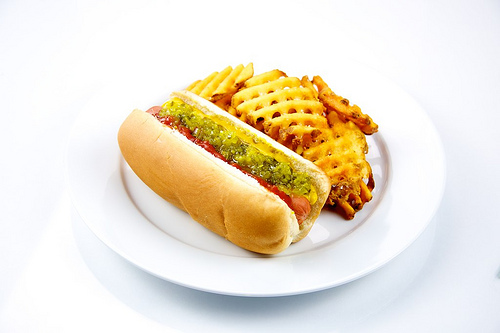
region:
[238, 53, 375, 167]
criss cut fries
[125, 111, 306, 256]
hotdog with bun and sauces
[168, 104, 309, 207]
mustard on a hotdog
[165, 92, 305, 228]
ketchup on a hotdog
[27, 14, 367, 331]
plate of food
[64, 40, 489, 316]
a white plate with food on it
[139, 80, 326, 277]
hotdog in a bun with mustard and ketchup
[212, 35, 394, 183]
potato fries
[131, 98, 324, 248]
A bun enclosing a hotdog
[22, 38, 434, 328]
A white clean plate containing good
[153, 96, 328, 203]
ketchup, mustard, and relish toppings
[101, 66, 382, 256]
a hotdog next to waffle fries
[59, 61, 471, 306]
a circular white plate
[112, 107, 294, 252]
a white bread hotdog bun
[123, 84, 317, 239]
a bun length hotdog.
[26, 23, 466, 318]
circular plate on a white surface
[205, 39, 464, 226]
waffle fries on a white plate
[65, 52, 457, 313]
a white plate under food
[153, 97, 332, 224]
relish in between ketchup and mustard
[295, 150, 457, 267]
light relflection on the plate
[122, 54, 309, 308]
hotdog sandwich on plate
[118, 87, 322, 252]
the hot dog on the plate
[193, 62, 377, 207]
the waffle fries on the plate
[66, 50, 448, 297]
the white circular plate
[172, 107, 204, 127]
the relish on the hot dog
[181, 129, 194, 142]
the ketchup on the hotdog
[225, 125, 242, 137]
the mustard on the hot dog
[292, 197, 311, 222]
the end of the hot dog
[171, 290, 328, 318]
the shadow from the plate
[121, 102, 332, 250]
the hot dog bun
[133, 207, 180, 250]
the ridge on the plate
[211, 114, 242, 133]
Mustard on a hotdog bun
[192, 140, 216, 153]
Ketchup on a hotdog bun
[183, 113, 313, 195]
Green relish on a hot dog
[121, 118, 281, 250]
Brown outside of a hot dog bun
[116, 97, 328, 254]
Hot dog on a white plate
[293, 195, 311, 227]
Tip of a hot dog on a bun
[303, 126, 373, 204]
Waffle fry on a plate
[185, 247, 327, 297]
Rim of a white plate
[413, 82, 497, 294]
White plate on a white table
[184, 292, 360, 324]
Shadow of a white plate on a table